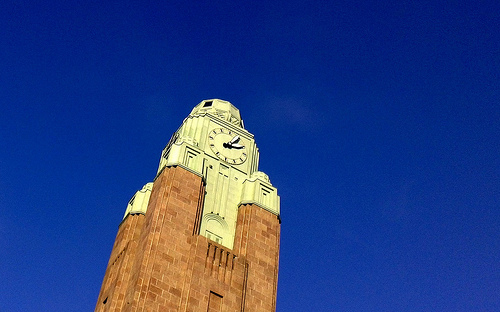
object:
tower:
[96, 98, 288, 309]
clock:
[207, 124, 250, 166]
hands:
[224, 142, 247, 151]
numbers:
[208, 131, 216, 142]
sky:
[1, 1, 500, 99]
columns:
[93, 166, 280, 310]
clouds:
[278, 94, 499, 180]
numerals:
[221, 154, 232, 164]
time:
[209, 128, 248, 166]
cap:
[187, 97, 245, 123]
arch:
[200, 211, 230, 232]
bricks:
[93, 166, 281, 309]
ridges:
[203, 242, 238, 286]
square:
[201, 98, 215, 109]